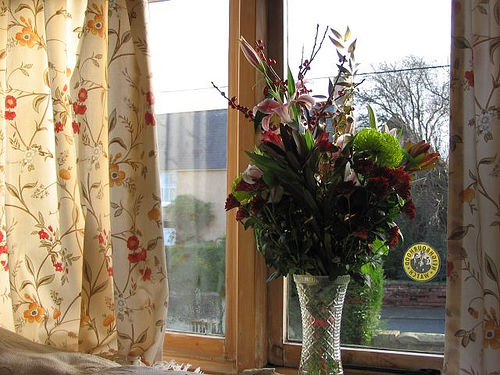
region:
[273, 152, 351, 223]
part of a plant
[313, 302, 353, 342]
part fo a vase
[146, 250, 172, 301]
part of a cloth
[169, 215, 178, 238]
part of a glass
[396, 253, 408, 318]
part of a circle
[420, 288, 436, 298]
part of a window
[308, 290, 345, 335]
part of a flass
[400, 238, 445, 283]
neighborhood watch sticker in a window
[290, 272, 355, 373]
a glass vase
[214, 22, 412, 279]
an arrangement of cut flowers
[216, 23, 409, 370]
flowers in a vase sitting in a window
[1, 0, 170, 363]
cream-colored window curtains with yellow and red flowers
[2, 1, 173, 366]
window curtains with a floral print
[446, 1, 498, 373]
window curtains with a floral print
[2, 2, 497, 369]
inside view of windows with curtains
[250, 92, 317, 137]
a lily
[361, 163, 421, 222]
carnations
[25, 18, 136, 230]
the curtain is white in colour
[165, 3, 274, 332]
the window is closed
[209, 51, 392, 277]
the flower is shiny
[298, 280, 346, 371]
the vase is crystal like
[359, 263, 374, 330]
the hedge is beautifully trimmed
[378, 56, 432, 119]
the tree is leafless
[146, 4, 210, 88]
the sky is white in colour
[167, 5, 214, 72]
the sky is cloudy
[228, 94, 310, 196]
the flowers are pink in colour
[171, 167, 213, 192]
the wall is white in colour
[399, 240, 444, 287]
a sticker in the window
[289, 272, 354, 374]
the glass vase on the window seal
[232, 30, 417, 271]
the plants in the vase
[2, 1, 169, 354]
the drape hanging down from the window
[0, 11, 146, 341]
flower print on the drapes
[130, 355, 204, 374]
the white frill on the edge of the blanket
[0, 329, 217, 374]
the brown blanket on the bed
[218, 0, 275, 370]
the window seal along the wall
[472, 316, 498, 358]
a sunflower print on the curtain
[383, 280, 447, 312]
the brick wall outside the window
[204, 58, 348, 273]
green plant in vase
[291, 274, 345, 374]
vase is clear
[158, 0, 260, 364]
brown frame on window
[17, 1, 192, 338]
tan orange and red curtain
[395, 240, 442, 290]
yellow sticker on window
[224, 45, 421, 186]
red and green flowers in vase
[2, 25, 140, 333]
flowers printed on curtain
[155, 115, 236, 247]
yellow building outside window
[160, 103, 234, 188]
yellow building with black roof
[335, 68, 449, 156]
bare tree outside window